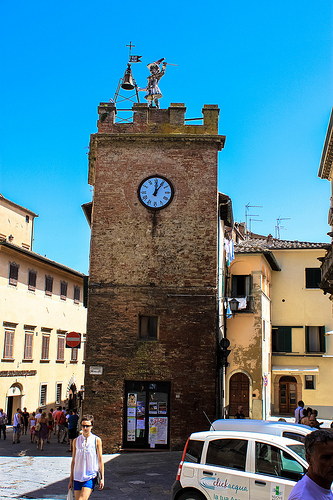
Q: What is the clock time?
A: One.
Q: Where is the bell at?
A: On the tower.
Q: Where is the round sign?
A: On the side of the tower.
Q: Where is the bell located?
A: Top building.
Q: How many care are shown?
A: Two.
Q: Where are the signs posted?
A: Door.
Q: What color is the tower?
A: Brown.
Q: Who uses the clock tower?
A: Public.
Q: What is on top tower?
A: Statue.